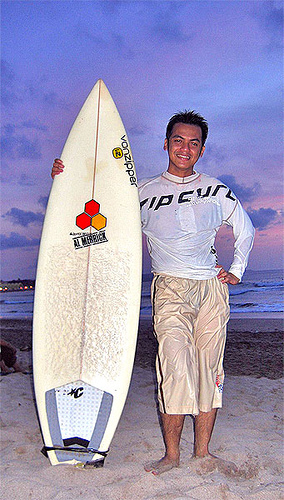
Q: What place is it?
A: It is a beach.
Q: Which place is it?
A: It is a beach.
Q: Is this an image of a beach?
A: Yes, it is showing a beach.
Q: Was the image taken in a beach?
A: Yes, it was taken in a beach.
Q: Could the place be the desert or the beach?
A: It is the beach.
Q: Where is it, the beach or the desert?
A: It is the beach.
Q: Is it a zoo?
A: No, it is a beach.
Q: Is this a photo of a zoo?
A: No, the picture is showing a beach.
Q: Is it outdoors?
A: Yes, it is outdoors.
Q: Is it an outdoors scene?
A: Yes, it is outdoors.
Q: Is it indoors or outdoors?
A: It is outdoors.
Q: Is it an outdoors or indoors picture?
A: It is outdoors.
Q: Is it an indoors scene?
A: No, it is outdoors.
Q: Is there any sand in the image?
A: Yes, there is sand.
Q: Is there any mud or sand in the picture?
A: Yes, there is sand.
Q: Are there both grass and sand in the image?
A: No, there is sand but no grass.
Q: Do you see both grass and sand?
A: No, there is sand but no grass.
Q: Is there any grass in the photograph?
A: No, there is no grass.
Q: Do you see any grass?
A: No, there is no grass.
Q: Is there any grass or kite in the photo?
A: No, there are no grass or kites.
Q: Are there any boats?
A: No, there are no boats.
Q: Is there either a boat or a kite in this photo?
A: No, there are no boats or kites.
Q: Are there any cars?
A: No, there are no cars.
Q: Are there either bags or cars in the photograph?
A: No, there are no cars or bags.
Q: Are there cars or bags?
A: No, there are no cars or bags.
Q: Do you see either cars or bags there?
A: No, there are no cars or bags.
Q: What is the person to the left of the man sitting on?
A: The person is sitting on the sand.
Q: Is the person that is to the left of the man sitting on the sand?
A: Yes, the person is sitting on the sand.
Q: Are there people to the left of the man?
A: Yes, there is a person to the left of the man.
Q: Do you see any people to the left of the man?
A: Yes, there is a person to the left of the man.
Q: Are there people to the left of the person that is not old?
A: Yes, there is a person to the left of the man.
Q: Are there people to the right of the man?
A: No, the person is to the left of the man.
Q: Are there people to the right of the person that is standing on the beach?
A: No, the person is to the left of the man.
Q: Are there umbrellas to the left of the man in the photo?
A: No, there is a person to the left of the man.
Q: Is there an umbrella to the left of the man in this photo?
A: No, there is a person to the left of the man.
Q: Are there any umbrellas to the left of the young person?
A: No, there is a person to the left of the man.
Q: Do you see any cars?
A: No, there are no cars.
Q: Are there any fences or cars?
A: No, there are no cars or fences.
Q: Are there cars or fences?
A: No, there are no cars or fences.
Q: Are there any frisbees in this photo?
A: No, there are no frisbees.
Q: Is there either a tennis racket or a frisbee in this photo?
A: No, there are no frisbees or rackets.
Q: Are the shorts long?
A: Yes, the shorts are long.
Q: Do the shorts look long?
A: Yes, the shorts are long.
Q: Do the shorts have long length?
A: Yes, the shorts are long.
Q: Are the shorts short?
A: No, the shorts are long.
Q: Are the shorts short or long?
A: The shorts are long.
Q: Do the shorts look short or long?
A: The shorts are long.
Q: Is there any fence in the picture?
A: No, there are no fences.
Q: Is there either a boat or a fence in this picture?
A: No, there are no fences or boats.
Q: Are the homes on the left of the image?
A: Yes, the homes are on the left of the image.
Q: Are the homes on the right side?
A: No, the homes are on the left of the image.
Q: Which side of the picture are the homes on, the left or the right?
A: The homes are on the left of the image.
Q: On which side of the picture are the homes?
A: The homes are on the left of the image.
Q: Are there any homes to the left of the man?
A: Yes, there are homes to the left of the man.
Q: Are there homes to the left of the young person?
A: Yes, there are homes to the left of the man.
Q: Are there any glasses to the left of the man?
A: No, there are homes to the left of the man.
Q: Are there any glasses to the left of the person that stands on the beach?
A: No, there are homes to the left of the man.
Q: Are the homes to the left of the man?
A: Yes, the homes are to the left of the man.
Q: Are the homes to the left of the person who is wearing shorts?
A: Yes, the homes are to the left of the man.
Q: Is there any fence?
A: No, there are no fences.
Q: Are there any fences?
A: No, there are no fences.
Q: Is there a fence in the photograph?
A: No, there are no fences.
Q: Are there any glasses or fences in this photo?
A: No, there are no fences or glasses.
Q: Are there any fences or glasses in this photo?
A: No, there are no fences or glasses.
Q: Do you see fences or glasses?
A: No, there are no fences or glasses.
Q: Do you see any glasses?
A: No, there are no glasses.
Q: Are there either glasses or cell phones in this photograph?
A: No, there are no glasses or cell phones.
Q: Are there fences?
A: No, there are no fences.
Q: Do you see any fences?
A: No, there are no fences.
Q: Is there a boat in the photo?
A: No, there are no boats.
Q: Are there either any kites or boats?
A: No, there are no boats or kites.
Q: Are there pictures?
A: No, there are no pictures.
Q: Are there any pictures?
A: No, there are no pictures.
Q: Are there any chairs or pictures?
A: No, there are no pictures or chairs.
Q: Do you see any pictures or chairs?
A: No, there are no pictures or chairs.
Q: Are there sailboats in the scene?
A: No, there are no sailboats.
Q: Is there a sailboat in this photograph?
A: No, there are no sailboats.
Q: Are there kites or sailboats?
A: No, there are no sailboats or kites.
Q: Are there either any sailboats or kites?
A: No, there are no sailboats or kites.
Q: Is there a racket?
A: No, there are no rackets.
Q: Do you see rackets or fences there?
A: No, there are no rackets or fences.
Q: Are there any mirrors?
A: No, there are no mirrors.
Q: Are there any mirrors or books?
A: No, there are no mirrors or books.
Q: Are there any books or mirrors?
A: No, there are no mirrors or books.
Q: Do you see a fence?
A: No, there are no fences.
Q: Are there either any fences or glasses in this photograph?
A: No, there are no fences or glasses.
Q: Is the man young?
A: Yes, the man is young.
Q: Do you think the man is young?
A: Yes, the man is young.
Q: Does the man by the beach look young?
A: Yes, the man is young.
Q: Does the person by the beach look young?
A: Yes, the man is young.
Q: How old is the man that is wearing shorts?
A: The man is young.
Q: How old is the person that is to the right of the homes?
A: The man is young.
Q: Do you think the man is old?
A: No, the man is young.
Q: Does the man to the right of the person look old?
A: No, the man is young.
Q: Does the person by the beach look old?
A: No, the man is young.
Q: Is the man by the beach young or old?
A: The man is young.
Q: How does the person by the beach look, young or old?
A: The man is young.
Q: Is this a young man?
A: Yes, this is a young man.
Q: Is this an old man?
A: No, this is a young man.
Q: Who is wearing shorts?
A: The man is wearing shorts.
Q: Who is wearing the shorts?
A: The man is wearing shorts.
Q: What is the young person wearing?
A: The man is wearing shorts.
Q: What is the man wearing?
A: The man is wearing shorts.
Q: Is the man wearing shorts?
A: Yes, the man is wearing shorts.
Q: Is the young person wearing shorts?
A: Yes, the man is wearing shorts.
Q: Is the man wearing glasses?
A: No, the man is wearing shorts.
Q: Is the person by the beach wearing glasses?
A: No, the man is wearing shorts.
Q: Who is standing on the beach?
A: The man is standing on the beach.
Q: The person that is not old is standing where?
A: The man is standing on the beach.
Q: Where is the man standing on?
A: The man is standing on the beach.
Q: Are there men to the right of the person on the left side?
A: Yes, there is a man to the right of the person.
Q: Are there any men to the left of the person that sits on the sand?
A: No, the man is to the right of the person.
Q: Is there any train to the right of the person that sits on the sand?
A: No, there is a man to the right of the person.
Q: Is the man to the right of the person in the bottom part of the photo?
A: Yes, the man is to the right of the person.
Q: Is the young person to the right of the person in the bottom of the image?
A: Yes, the man is to the right of the person.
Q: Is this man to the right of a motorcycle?
A: No, the man is to the right of the person.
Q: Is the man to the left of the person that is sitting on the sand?
A: No, the man is to the right of the person.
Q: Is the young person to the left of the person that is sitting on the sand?
A: No, the man is to the right of the person.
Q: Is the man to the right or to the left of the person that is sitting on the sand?
A: The man is to the right of the person.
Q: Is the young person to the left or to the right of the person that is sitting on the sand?
A: The man is to the right of the person.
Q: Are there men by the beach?
A: Yes, there is a man by the beach.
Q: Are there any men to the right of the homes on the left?
A: Yes, there is a man to the right of the homes.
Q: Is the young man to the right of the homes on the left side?
A: Yes, the man is to the right of the homes.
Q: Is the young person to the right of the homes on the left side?
A: Yes, the man is to the right of the homes.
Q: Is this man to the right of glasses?
A: No, the man is to the right of the homes.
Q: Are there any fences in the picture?
A: No, there are no fences.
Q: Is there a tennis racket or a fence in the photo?
A: No, there are no fences or rackets.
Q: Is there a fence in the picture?
A: No, there are no fences.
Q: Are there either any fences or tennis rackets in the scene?
A: No, there are no fences or tennis rackets.